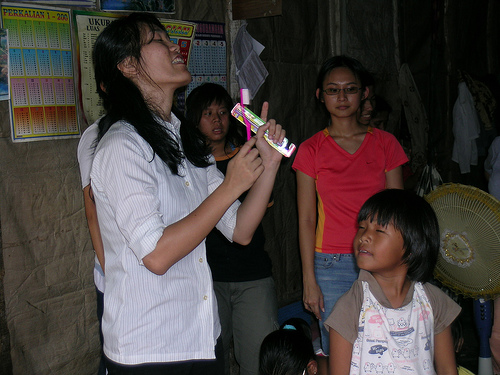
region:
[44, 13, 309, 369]
lady holding toothbrush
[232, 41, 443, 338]
lady wearing red top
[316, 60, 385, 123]
lady wearing glasses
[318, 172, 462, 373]
child sitting looking at lady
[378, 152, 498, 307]
yellow fan with sparkles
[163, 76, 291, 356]
lady wearing orange and black shirt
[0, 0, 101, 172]
colorful calendar on wall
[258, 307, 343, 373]
lady wearing blue hair tie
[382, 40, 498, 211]
hanging coats in background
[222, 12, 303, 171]
paper on the wall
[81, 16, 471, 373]
A group of people standing around in a room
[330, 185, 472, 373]
A young child sitting down in a chair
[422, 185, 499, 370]
A fan sitting off to the side.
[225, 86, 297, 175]
Toothbrushes in the woman's hands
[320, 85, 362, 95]
The glasses on the other woman's face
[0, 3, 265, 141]
Signs on the wall behind the women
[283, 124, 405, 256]
The pink and yellow shirt on the woman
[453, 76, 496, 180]
Clothes hanging off to the side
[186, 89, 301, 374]
A young girl standing in the back.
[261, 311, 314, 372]
The head of somebody sitting down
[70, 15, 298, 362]
The woman is giving a presentation.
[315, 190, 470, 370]
The child is wearing a t-shirt.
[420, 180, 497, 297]
A fan.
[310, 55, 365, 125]
The woman is wearing glasses.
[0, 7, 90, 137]
A poster.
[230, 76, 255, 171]
A pink toothbrush.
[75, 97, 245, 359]
The shirt has vertical stripes on it.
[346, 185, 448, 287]
The child has black hair.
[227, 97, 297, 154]
The woman is holding the packaging a toothbrush comes in.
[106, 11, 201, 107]
The woman's eyes are closed.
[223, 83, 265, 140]
pink toothbrush in woman's hand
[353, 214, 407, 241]
child with eyes closed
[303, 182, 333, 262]
gold part of red shirt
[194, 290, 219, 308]
brown button on white shirt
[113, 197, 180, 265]
rolled up sleeve on white shir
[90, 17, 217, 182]
woman's long stringy black hair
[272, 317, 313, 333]
blue hair holder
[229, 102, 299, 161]
woman holding tooth paste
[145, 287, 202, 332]
stripes on woman's shirt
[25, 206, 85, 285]
wrinkled brown paper on wall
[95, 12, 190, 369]
this is a woman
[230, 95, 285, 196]
the woman is holding a toothbrush and a toothpaste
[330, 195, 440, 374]
this is a small boy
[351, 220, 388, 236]
the boys eyes are closed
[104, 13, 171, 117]
the womans head is facing upwards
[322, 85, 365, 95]
the lady is wearing spectacles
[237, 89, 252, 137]
the toothbrush is pink in color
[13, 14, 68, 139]
a calendar is on the wall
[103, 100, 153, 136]
the woman has long hair